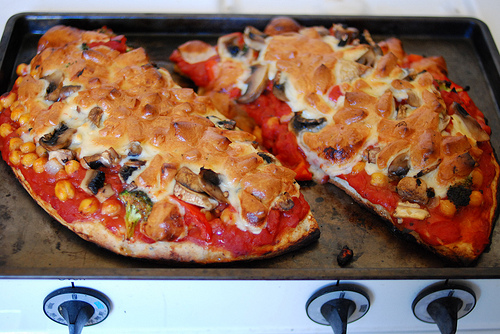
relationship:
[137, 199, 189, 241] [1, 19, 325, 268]
mushroom on pizza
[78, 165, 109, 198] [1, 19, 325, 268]
mushroom on pizza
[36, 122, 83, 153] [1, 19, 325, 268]
mushroom on pizza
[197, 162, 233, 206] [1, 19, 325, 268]
mushroom on pizza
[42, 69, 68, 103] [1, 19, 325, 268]
mushroom on pizza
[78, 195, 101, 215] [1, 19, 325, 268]
corn on pizza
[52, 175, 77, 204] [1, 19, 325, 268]
corn on pizza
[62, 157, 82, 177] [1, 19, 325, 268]
corn on pizza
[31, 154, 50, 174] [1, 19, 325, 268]
corn on pizza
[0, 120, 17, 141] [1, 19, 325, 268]
corn on pizza